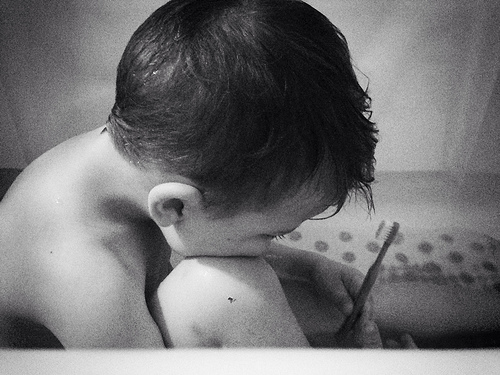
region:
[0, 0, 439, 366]
Child resting his head on his knee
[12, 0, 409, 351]
Child holding a toothbrush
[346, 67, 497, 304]
Shower curtain with polka dots at the bottom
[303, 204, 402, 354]
Small hand holding a toothbrush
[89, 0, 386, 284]
Boy with brown hair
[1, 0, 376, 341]
Naked boy in a bathroom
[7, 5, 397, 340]
Boy with wet hair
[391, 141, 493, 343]
Bath tub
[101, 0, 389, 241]
Short brown hair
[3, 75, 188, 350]
The back of a child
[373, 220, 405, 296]
Toothbrush in child's hand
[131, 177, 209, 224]
Ear on the side of a boy's head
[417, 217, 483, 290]
dots in the tub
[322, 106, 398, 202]
combed wet hair on boy's head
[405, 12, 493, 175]
Clear shower curtain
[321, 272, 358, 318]
thumb on left hand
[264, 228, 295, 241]
Eyelashes of little boy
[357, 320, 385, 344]
thumb of right hand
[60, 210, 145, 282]
Bony shoulder of little boy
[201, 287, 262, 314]
Black spot on knee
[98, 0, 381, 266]
the head of a person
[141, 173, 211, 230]
the ear of a person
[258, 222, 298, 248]
the eye of a person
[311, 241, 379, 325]
the hand of a person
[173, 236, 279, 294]
the knee of a person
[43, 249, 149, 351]
the shoulder of a person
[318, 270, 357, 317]
the thumb of a person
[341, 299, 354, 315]
the thumb nail of a person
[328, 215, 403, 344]
a toothbrush in the child's hands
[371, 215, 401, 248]
the bristles of a toothbrush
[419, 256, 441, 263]
THE HOLE IS BLACK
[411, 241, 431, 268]
THE HOLE IS BLACK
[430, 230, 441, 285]
THE HOLE IS BLACK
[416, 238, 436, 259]
THE HOLE IS BLACK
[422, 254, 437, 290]
THE HOLE IS BLACK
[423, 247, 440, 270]
THE HOLE IS BLACK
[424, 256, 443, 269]
THE HOLE IS BLACK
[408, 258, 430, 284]
THE HOLE IS BLACK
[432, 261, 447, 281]
THE HOLE IS BLACK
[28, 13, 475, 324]
the photo is black and white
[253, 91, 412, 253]
the hair is wet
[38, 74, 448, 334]
the boy is young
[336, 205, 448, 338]
he holds a toothbrush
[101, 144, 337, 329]
the boy rests his head on his knee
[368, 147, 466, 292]
the bathtub has slipping dots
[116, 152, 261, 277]
this is a human ear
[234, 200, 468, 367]
the boy looks at his toothbrush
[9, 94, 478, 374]
the boy is in a bathtub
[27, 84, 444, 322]
the toothbrush is in his hands